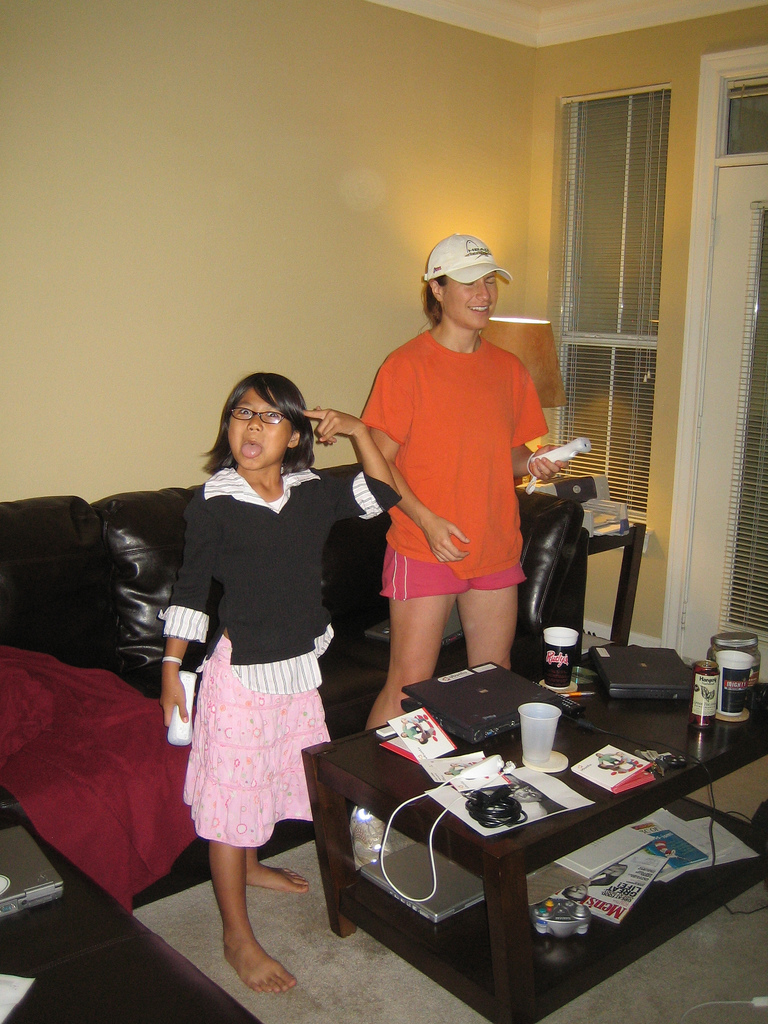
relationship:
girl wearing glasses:
[169, 344, 360, 547] [219, 402, 306, 428]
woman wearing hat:
[398, 213, 554, 405] [416, 215, 531, 302]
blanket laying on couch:
[6, 645, 190, 853] [3, 483, 294, 892]